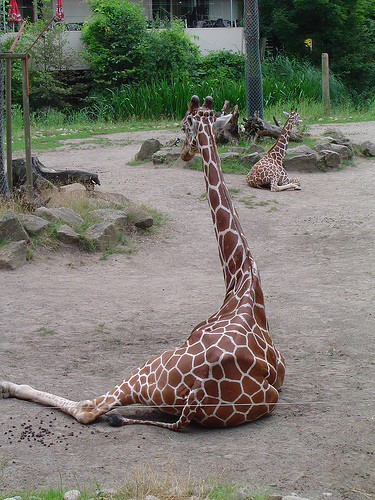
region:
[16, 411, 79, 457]
Giraffe food on the ground.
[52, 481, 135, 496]
Big rocks in the dirt.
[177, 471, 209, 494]
Patch of green and brown grass.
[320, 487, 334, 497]
Small white rock in the dirt.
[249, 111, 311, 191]
Giraffe laying down in the dirt.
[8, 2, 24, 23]
Red and white umbrella on the porch.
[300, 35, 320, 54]
Yellow flag in the trees.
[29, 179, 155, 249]
Big rocks in the dirt.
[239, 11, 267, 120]
Fence wrapped around the tree.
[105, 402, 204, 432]
Back of giraffe's tail.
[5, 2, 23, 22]
Red and white outdoor umbrella.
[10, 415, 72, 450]
Giraffe raisin like feces on ground.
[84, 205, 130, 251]
Large rock on ground.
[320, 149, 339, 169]
Boulder along side tree.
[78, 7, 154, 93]
Tall bushes alongside fence.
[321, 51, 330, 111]
Headless tree stump alongside road.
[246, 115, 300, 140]
Dead tree stump on ground.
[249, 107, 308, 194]
Baby giraffe resting on ground.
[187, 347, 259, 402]
Brown and white pattern on giraffe's.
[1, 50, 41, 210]
Metal structure in zoo near giraffe's.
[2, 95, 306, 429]
Two giraffes laying down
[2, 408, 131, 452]
Giraffe dung pellets on ground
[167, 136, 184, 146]
Landscaping light pointed at tall tree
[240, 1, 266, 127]
Tall tree trunk protected by chain-link fence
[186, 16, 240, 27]
Patio furniture on porch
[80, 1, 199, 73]
Large bushy green bush in front of white wall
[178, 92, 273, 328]
Giraffe has a long erect neck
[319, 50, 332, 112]
Solid wooden fence post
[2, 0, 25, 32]
Red patio shade-umbrella with white stripes on porch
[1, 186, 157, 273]
Pile of medium-sized lanscaping rocks with tufts of grass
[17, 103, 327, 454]
two giraffes in a pen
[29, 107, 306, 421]
two giraffes laying on the ground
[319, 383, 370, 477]
grey dirt of the ground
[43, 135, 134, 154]
sparse green grass growing on the ground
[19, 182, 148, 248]
green grass growing out of the rocks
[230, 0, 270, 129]
grey chain linked fence wrapped around the tree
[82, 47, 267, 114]
green plants growing on the edge of the enclosure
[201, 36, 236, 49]
white surface of the wall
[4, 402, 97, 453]
brown animal droppings on the ground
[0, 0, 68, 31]
two red umbrellas on the patio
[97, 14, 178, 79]
leaves on a tree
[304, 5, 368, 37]
trees in the distance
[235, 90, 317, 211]
baby giraffe on ground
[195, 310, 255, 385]
brown spots on animal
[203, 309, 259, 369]
white lines on animal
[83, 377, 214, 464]
tail of the giraffe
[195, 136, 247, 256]
neck of the giraffe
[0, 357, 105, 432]
leg of the giraffe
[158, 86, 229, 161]
head of the giraffe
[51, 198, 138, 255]
rocks on the ground